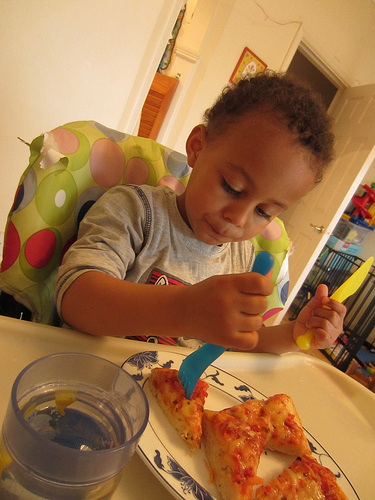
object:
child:
[52, 69, 349, 354]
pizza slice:
[149, 366, 208, 451]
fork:
[179, 252, 274, 400]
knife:
[296, 254, 375, 349]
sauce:
[172, 381, 182, 394]